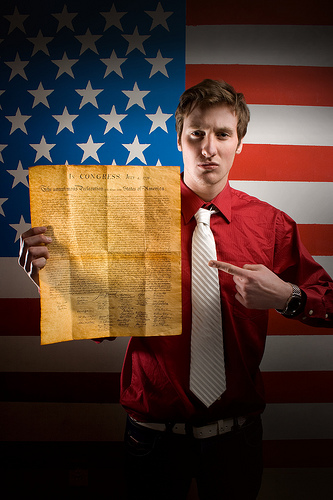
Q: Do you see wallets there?
A: No, there are no wallets.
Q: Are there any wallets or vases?
A: No, there are no wallets or vases.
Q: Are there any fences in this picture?
A: No, there are no fences.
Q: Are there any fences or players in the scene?
A: No, there are no fences or players.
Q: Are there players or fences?
A: No, there are no fences or players.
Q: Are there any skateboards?
A: No, there are no skateboards.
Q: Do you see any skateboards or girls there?
A: No, there are no skateboards or girls.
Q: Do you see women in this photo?
A: No, there are no women.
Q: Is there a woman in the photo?
A: No, there are no women.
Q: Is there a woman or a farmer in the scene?
A: No, there are no women or farmers.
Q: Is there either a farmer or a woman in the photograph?
A: No, there are no women or farmers.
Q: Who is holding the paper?
A: The man is holding the paper.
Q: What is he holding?
A: The man is holding the paper.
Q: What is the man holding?
A: The man is holding the paper.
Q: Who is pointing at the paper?
A: The man is pointing at the paper.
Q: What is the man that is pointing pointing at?
A: The man is pointing at the paper.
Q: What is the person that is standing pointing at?
A: The man is pointing at the paper.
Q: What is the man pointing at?
A: The man is pointing at the paper.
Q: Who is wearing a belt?
A: The man is wearing a belt.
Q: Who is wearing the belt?
A: The man is wearing a belt.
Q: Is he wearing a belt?
A: Yes, the man is wearing a belt.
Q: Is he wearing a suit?
A: No, the man is wearing a belt.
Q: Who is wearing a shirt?
A: The man is wearing a shirt.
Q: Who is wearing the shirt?
A: The man is wearing a shirt.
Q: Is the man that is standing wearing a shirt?
A: Yes, the man is wearing a shirt.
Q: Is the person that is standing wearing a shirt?
A: Yes, the man is wearing a shirt.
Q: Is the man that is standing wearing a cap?
A: No, the man is wearing a shirt.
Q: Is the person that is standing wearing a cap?
A: No, the man is wearing a shirt.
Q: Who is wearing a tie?
A: The man is wearing a tie.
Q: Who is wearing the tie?
A: The man is wearing a tie.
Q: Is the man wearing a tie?
A: Yes, the man is wearing a tie.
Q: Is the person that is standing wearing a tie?
A: Yes, the man is wearing a tie.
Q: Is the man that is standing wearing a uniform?
A: No, the man is wearing a tie.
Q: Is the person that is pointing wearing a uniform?
A: No, the man is wearing a tie.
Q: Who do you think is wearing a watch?
A: The man is wearing a watch.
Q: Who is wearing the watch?
A: The man is wearing a watch.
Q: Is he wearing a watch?
A: Yes, the man is wearing a watch.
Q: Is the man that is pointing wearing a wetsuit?
A: No, the man is wearing a watch.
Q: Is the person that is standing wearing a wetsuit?
A: No, the man is wearing a watch.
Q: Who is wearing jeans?
A: The man is wearing jeans.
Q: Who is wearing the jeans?
A: The man is wearing jeans.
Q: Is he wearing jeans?
A: Yes, the man is wearing jeans.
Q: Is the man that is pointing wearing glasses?
A: No, the man is wearing jeans.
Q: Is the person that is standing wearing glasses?
A: No, the man is wearing jeans.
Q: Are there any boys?
A: No, there are no boys.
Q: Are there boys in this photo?
A: No, there are no boys.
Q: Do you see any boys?
A: No, there are no boys.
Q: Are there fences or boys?
A: No, there are no boys or fences.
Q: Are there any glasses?
A: No, there are no glasses.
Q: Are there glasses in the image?
A: No, there are no glasses.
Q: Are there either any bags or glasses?
A: No, there are no glasses or bags.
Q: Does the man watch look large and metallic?
A: Yes, the watch is large and metallic.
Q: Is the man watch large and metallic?
A: Yes, the watch is large and metallic.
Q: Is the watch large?
A: Yes, the watch is large.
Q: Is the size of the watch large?
A: Yes, the watch is large.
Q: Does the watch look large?
A: Yes, the watch is large.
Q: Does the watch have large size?
A: Yes, the watch is large.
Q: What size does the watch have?
A: The watch has large size.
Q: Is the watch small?
A: No, the watch is large.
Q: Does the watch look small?
A: No, the watch is large.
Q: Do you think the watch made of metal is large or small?
A: The watch is large.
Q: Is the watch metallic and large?
A: Yes, the watch is metallic and large.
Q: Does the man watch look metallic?
A: Yes, the watch is metallic.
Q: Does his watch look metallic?
A: Yes, the watch is metallic.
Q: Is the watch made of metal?
A: Yes, the watch is made of metal.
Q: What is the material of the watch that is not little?
A: The watch is made of metal.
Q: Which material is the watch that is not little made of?
A: The watch is made of metal.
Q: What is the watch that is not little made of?
A: The watch is made of metal.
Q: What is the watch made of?
A: The watch is made of metal.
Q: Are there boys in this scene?
A: No, there are no boys.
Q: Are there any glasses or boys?
A: No, there are no boys or glasses.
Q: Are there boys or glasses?
A: No, there are no boys or glasses.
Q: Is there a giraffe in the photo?
A: No, there are no giraffes.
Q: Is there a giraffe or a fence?
A: No, there are no giraffes or fences.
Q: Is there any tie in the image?
A: Yes, there is a tie.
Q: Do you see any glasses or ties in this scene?
A: Yes, there is a tie.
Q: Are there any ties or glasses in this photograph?
A: Yes, there is a tie.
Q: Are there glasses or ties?
A: Yes, there is a tie.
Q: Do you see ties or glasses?
A: Yes, there is a tie.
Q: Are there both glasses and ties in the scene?
A: No, there is a tie but no glasses.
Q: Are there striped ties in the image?
A: Yes, there is a striped tie.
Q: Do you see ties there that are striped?
A: Yes, there is a tie that is striped.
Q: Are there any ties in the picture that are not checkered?
A: Yes, there is a striped tie.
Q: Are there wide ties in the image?
A: Yes, there is a wide tie.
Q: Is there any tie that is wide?
A: Yes, there is a tie that is wide.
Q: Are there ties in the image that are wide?
A: Yes, there is a tie that is wide.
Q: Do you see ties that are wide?
A: Yes, there is a tie that is wide.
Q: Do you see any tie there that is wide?
A: Yes, there is a tie that is wide.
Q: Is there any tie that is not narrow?
A: Yes, there is a wide tie.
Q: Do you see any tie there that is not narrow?
A: Yes, there is a wide tie.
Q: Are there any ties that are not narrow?
A: Yes, there is a wide tie.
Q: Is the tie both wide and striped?
A: Yes, the tie is wide and striped.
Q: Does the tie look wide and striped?
A: Yes, the tie is wide and striped.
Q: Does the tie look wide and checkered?
A: No, the tie is wide but striped.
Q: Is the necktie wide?
A: Yes, the necktie is wide.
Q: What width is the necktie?
A: The necktie is wide.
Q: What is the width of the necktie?
A: The necktie is wide.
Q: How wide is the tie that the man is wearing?
A: The necktie is wide.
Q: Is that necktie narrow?
A: No, the necktie is wide.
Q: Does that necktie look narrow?
A: No, the necktie is wide.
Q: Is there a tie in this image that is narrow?
A: No, there is a tie but it is wide.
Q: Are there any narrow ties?
A: No, there is a tie but it is wide.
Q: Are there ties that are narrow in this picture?
A: No, there is a tie but it is wide.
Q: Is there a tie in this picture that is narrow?
A: No, there is a tie but it is wide.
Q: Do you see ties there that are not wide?
A: No, there is a tie but it is wide.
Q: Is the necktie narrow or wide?
A: The necktie is wide.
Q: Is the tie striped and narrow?
A: No, the tie is striped but wide.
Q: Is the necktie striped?
A: Yes, the necktie is striped.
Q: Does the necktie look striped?
A: Yes, the necktie is striped.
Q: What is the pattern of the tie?
A: The necktie is striped.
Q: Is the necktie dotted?
A: No, the necktie is striped.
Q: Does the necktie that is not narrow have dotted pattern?
A: No, the tie is striped.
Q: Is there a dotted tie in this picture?
A: No, there is a tie but it is striped.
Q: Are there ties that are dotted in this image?
A: No, there is a tie but it is striped.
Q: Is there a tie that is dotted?
A: No, there is a tie but it is striped.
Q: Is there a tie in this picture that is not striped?
A: No, there is a tie but it is striped.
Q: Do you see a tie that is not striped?
A: No, there is a tie but it is striped.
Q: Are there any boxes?
A: No, there are no boxes.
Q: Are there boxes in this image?
A: No, there are no boxes.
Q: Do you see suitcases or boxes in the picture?
A: No, there are no boxes or suitcases.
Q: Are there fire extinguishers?
A: No, there are no fire extinguishers.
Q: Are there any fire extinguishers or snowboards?
A: No, there are no fire extinguishers or snowboards.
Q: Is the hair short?
A: Yes, the hair is short.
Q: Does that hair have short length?
A: Yes, the hair is short.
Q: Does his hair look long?
A: No, the hair is short.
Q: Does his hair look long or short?
A: The hair is short.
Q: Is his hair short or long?
A: The hair is short.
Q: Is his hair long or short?
A: The hair is short.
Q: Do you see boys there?
A: No, there are no boys.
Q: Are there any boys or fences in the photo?
A: No, there are no boys or fences.